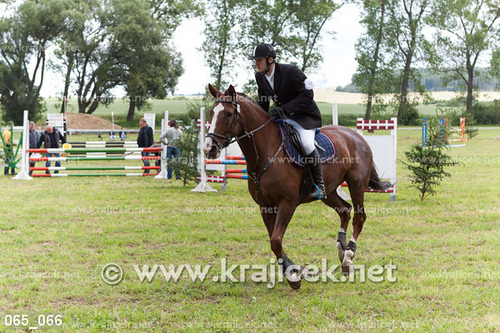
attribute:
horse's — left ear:
[198, 80, 396, 295]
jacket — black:
[135, 121, 160, 146]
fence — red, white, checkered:
[335, 99, 401, 172]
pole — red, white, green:
[29, 148, 163, 150]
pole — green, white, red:
[29, 155, 161, 161]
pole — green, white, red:
[28, 163, 158, 168]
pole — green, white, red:
[30, 170, 159, 177]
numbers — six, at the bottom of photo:
[0, 312, 62, 332]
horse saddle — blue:
[283, 123, 338, 164]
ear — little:
[207, 84, 222, 97]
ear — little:
[226, 84, 238, 99]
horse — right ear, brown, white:
[193, 83, 393, 288]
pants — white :
[278, 117, 321, 156]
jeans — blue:
[163, 146, 181, 176]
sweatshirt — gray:
[157, 126, 182, 148]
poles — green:
[28, 145, 165, 181]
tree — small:
[411, 111, 454, 218]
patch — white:
[303, 79, 315, 88]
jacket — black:
[268, 63, 319, 125]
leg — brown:
[346, 170, 371, 270]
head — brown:
[200, 81, 247, 163]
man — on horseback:
[253, 42, 327, 200]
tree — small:
[396, 114, 454, 204]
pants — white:
[291, 120, 320, 160]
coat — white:
[37, 120, 67, 163]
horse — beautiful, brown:
[172, 70, 394, 283]